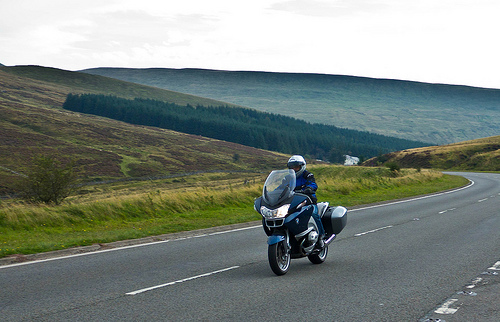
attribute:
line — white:
[435, 200, 457, 219]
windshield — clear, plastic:
[248, 169, 299, 206]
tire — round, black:
[306, 243, 328, 263]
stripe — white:
[359, 189, 486, 251]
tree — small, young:
[12, 152, 85, 206]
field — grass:
[2, 67, 469, 267]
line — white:
[352, 222, 394, 242]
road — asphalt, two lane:
[0, 170, 498, 320]